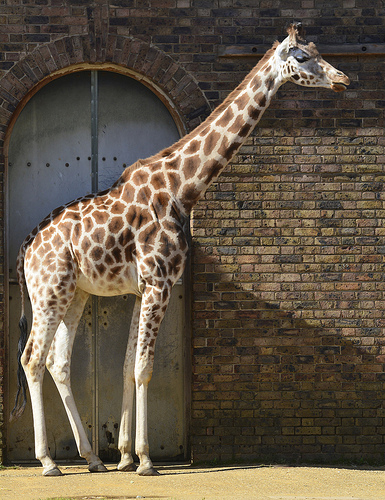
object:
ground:
[0, 460, 384, 499]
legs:
[20, 246, 78, 431]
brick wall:
[1, 0, 384, 472]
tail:
[8, 256, 26, 422]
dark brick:
[313, 200, 342, 211]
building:
[1, 2, 384, 474]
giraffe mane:
[118, 42, 277, 171]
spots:
[14, 54, 335, 382]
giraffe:
[9, 22, 350, 476]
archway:
[0, 32, 196, 469]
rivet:
[108, 150, 120, 166]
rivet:
[60, 160, 73, 171]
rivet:
[22, 157, 36, 171]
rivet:
[174, 292, 185, 305]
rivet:
[100, 307, 111, 319]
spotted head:
[273, 16, 354, 98]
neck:
[138, 51, 287, 213]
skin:
[93, 199, 155, 251]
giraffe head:
[275, 22, 349, 91]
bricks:
[0, 0, 102, 62]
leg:
[45, 287, 89, 452]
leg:
[132, 223, 189, 447]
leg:
[120, 291, 142, 413]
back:
[19, 37, 287, 251]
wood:
[215, 41, 384, 58]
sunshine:
[0, 32, 381, 498]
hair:
[8, 310, 32, 426]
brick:
[254, 230, 363, 416]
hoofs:
[41, 462, 64, 479]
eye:
[291, 51, 314, 68]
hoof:
[88, 462, 109, 471]